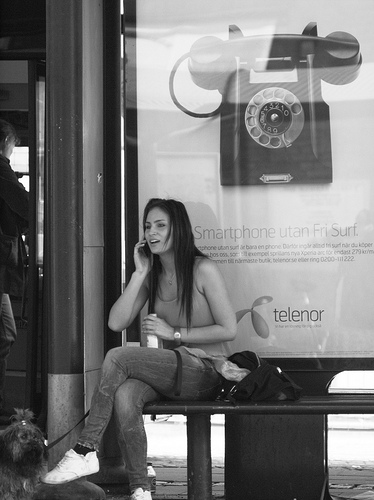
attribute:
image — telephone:
[169, 22, 361, 188]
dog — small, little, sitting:
[0, 407, 50, 499]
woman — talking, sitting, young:
[40, 198, 236, 499]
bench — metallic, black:
[142, 392, 373, 499]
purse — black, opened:
[217, 351, 303, 404]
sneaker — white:
[40, 445, 100, 485]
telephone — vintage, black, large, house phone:
[168, 21, 362, 186]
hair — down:
[144, 198, 212, 334]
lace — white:
[55, 452, 73, 472]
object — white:
[146, 313, 159, 348]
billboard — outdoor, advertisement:
[138, 0, 362, 357]